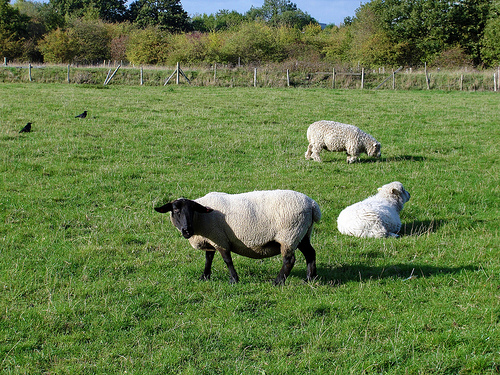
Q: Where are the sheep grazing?
A: In the field.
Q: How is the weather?
A: Sunny.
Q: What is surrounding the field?
A: A fence.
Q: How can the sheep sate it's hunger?
A: By eating grass.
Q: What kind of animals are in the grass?
A: Sheep.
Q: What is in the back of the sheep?
A: Fence.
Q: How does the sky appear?
A: Blue and clear.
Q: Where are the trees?
A: Behind fence.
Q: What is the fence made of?
A: Metal.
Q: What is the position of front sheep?
A: Standing.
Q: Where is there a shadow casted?
A: On grass.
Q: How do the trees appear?
A: Green and lush.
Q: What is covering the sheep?
A: Wool.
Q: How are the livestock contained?
A: By a wood and metal fence.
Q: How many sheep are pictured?
A: 3.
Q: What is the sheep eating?
A: Grass.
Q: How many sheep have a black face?
A: 1.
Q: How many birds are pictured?
A: 2.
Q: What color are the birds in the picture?
A: Black.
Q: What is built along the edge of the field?
A: A fence.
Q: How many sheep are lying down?
A: 1.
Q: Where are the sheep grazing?
A: In a field.